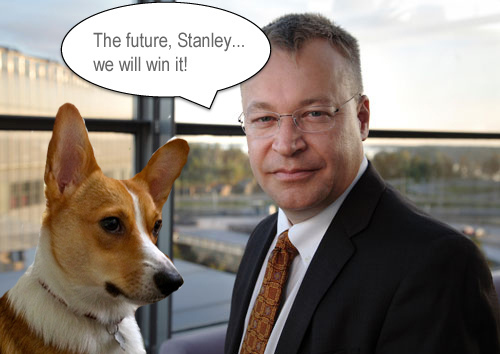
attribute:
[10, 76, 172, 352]
dog — brown, white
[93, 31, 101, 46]
letter — black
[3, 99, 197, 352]
dog — brown, white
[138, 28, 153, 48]
letter — black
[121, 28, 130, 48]
letter f — black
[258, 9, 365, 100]
hair — short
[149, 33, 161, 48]
letter — black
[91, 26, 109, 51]
letter — black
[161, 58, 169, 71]
letter — black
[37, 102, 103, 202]
dog's ear — up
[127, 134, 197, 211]
dog's ear — up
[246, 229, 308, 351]
tie — brown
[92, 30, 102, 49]
letter — black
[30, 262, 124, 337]
neck — white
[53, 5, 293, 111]
bubble — white